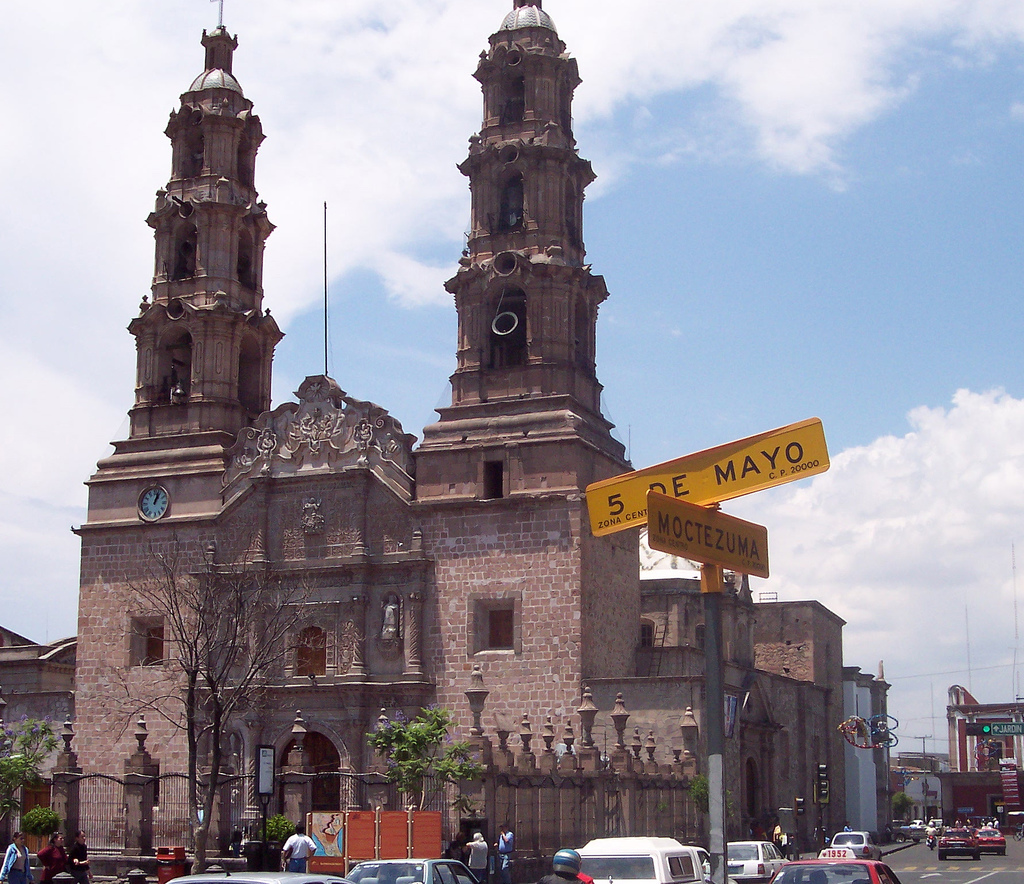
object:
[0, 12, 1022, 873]
outdoors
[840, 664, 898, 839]
building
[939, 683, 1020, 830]
building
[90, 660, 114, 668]
brick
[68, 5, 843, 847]
building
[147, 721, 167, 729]
brick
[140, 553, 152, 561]
brick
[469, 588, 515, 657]
window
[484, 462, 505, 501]
window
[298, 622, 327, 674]
window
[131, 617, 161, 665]
window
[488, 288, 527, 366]
window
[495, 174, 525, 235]
window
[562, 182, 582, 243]
window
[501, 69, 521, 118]
window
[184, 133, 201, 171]
window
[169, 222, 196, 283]
window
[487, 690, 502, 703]
brick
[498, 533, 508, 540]
brick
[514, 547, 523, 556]
brick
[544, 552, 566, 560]
brick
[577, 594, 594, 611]
brick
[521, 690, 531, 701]
brick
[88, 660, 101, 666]
brick